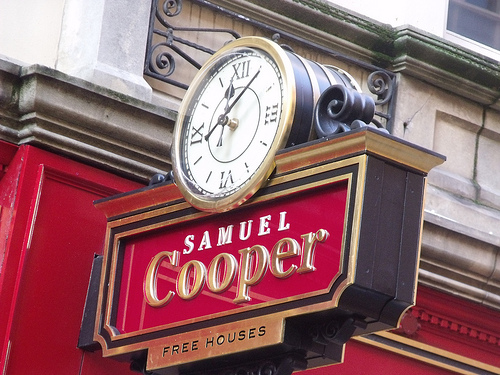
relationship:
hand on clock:
[215, 73, 237, 147] [160, 30, 328, 242]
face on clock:
[188, 81, 281, 166] [149, 10, 358, 228]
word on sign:
[121, 235, 363, 314] [80, 189, 398, 336]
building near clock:
[9, 5, 120, 340] [129, 22, 324, 201]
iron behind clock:
[150, 1, 391, 128] [172, 35, 363, 223]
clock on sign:
[170, 36, 296, 214] [95, 127, 450, 369]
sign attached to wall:
[95, 36, 440, 374] [0, 2, 492, 365]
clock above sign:
[170, 36, 296, 214] [95, 127, 450, 369]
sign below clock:
[95, 127, 450, 369] [172, 35, 363, 223]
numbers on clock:
[240, 59, 251, 79] [170, 36, 296, 214]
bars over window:
[147, 2, 398, 141] [139, 7, 408, 155]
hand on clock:
[215, 73, 237, 147] [162, 36, 307, 229]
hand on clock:
[215, 73, 237, 147] [169, 30, 298, 210]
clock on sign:
[163, 33, 303, 216] [64, 27, 444, 370]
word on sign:
[173, 205, 296, 265] [90, 36, 445, 374]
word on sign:
[143, 229, 327, 307] [95, 127, 450, 369]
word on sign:
[201, 314, 276, 354] [74, 108, 450, 372]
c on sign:
[135, 237, 192, 319] [65, 59, 445, 369]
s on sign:
[178, 226, 198, 259] [74, 108, 450, 372]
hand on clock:
[210, 61, 243, 151] [161, 23, 316, 215]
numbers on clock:
[185, 51, 288, 199] [158, 21, 325, 227]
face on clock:
[178, 47, 283, 198] [162, 28, 341, 219]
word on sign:
[182, 211, 291, 255] [104, 147, 372, 343]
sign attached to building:
[90, 36, 445, 374] [3, 3, 481, 373]